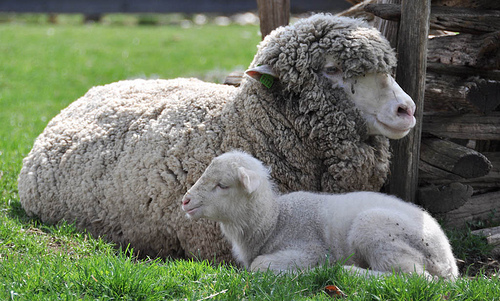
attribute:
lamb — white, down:
[177, 150, 468, 285]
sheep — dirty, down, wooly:
[268, 16, 410, 179]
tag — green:
[258, 74, 281, 97]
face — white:
[189, 149, 262, 234]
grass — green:
[363, 285, 381, 298]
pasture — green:
[25, 49, 65, 70]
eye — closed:
[214, 179, 230, 192]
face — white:
[327, 41, 414, 153]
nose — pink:
[177, 191, 192, 207]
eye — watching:
[325, 65, 341, 77]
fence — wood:
[262, 6, 295, 20]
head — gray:
[239, 6, 422, 152]